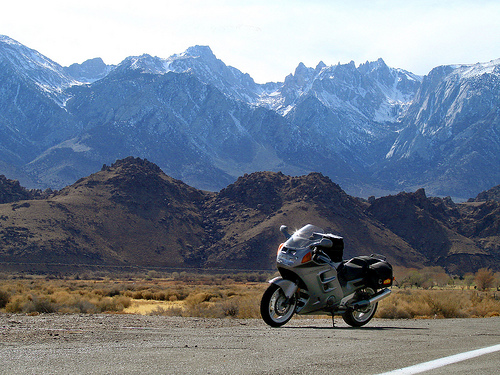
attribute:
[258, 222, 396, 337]
motorcycle — grey, sitting, black, silver, sleek, upright, parked, high performance, empty, waiting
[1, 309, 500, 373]
road — grey, asphalt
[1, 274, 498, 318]
grass — brown, patchy, dry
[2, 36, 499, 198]
mountains — blue, soaring, background, large, behind, distant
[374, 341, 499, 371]
line — white, painted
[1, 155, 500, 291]
hills — brown, low, rolling, small, close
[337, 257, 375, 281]
seat — black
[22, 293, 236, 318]
shrubs — dry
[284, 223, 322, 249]
windshield — sloping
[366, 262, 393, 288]
container — storage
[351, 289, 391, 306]
pipe — exhaust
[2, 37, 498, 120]
tops — snow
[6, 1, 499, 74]
sky — blue, pale